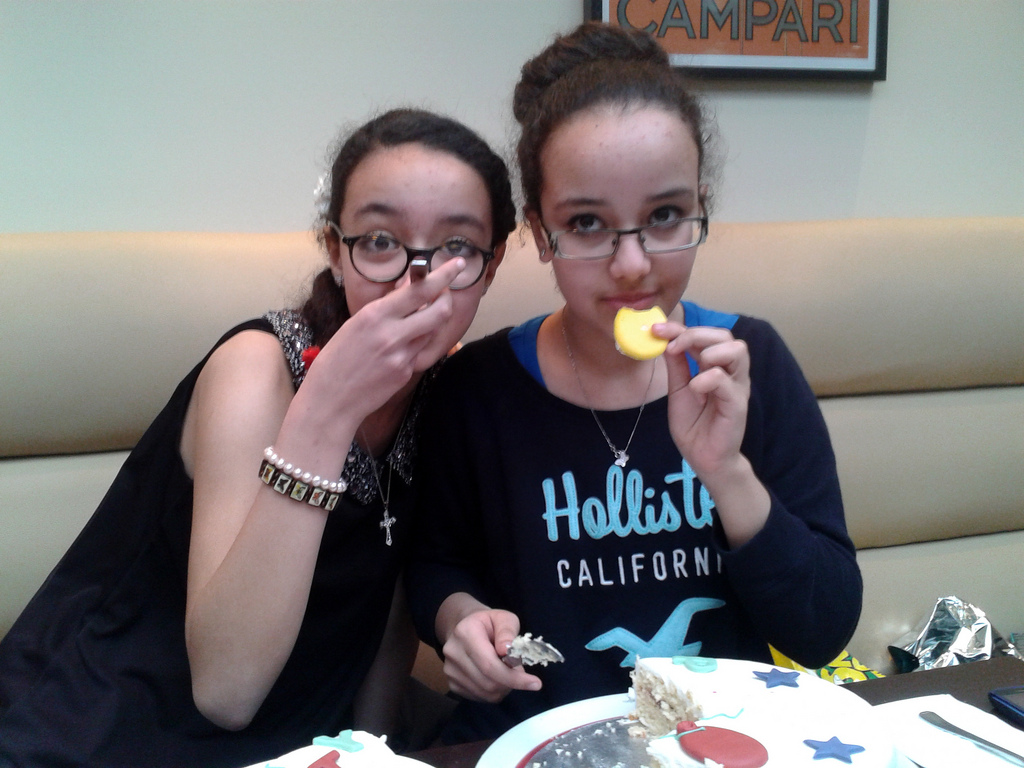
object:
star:
[796, 728, 867, 763]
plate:
[469, 691, 679, 765]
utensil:
[917, 708, 1019, 764]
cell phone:
[981, 675, 1020, 726]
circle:
[668, 715, 766, 766]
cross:
[372, 500, 405, 548]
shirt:
[5, 310, 408, 763]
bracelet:
[257, 444, 345, 511]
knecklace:
[607, 302, 678, 361]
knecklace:
[266, 383, 401, 463]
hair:
[510, 22, 701, 189]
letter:
[556, 560, 573, 588]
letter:
[665, 454, 708, 528]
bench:
[2, 215, 1021, 681]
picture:
[592, 4, 887, 82]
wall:
[5, 5, 1023, 228]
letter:
[581, 497, 606, 540]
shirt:
[400, 305, 862, 729]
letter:
[540, 470, 579, 542]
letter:
[605, 466, 622, 539]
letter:
[624, 469, 644, 535]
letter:
[644, 488, 655, 534]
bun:
[510, 27, 666, 113]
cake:
[501, 634, 566, 668]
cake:
[622, 652, 906, 765]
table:
[873, 653, 1021, 733]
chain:
[358, 422, 408, 507]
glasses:
[521, 202, 707, 260]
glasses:
[332, 223, 494, 290]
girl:
[388, 30, 850, 746]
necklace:
[561, 301, 663, 466]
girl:
[0, 104, 521, 768]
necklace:
[362, 416, 405, 547]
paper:
[887, 595, 1004, 677]